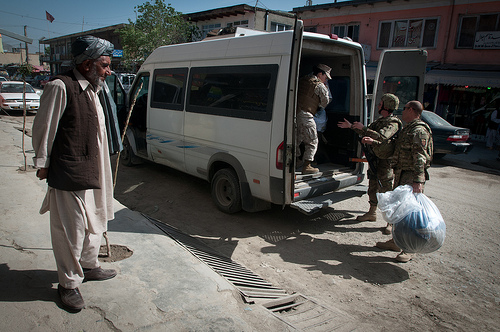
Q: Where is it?
A: This is at the street.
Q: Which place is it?
A: It is a street.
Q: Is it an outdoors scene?
A: Yes, it is outdoors.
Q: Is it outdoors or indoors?
A: It is outdoors.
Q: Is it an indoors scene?
A: No, it is outdoors.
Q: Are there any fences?
A: No, there are no fences.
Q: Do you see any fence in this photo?
A: No, there are no fences.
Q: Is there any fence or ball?
A: No, there are no fences or balls.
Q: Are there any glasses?
A: No, there are no glasses.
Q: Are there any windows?
A: Yes, there is a window.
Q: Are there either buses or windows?
A: Yes, there is a window.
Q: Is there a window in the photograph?
A: Yes, there are windows.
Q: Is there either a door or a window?
A: Yes, there are windows.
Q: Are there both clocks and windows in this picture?
A: No, there are windows but no clocks.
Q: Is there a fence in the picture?
A: No, there are no fences.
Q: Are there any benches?
A: No, there are no benches.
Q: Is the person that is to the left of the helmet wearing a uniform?
A: Yes, the person is wearing a uniform.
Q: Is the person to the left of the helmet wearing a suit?
A: No, the person is wearing a uniform.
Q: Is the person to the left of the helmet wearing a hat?
A: Yes, the person is wearing a hat.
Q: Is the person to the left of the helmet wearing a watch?
A: No, the person is wearing a hat.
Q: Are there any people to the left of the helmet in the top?
A: Yes, there is a person to the left of the helmet.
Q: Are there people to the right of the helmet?
A: No, the person is to the left of the helmet.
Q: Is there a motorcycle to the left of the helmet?
A: No, there is a person to the left of the helmet.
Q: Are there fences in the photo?
A: No, there are no fences.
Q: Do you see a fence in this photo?
A: No, there are no fences.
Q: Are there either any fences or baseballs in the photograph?
A: No, there are no fences or baseballs.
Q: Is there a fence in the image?
A: No, there are no fences.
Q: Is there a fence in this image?
A: No, there are no fences.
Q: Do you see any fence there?
A: No, there are no fences.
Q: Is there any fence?
A: No, there are no fences.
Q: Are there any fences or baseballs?
A: No, there are no fences or baseballs.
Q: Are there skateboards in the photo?
A: No, there are no skateboards.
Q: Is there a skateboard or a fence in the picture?
A: No, there are no skateboards or fences.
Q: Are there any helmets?
A: Yes, there is a helmet.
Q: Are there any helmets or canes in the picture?
A: Yes, there is a helmet.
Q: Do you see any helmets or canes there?
A: Yes, there is a helmet.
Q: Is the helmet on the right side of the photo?
A: Yes, the helmet is on the right of the image.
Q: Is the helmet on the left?
A: No, the helmet is on the right of the image.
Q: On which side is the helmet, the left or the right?
A: The helmet is on the right of the image.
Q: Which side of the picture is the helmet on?
A: The helmet is on the right of the image.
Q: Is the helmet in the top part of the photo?
A: Yes, the helmet is in the top of the image.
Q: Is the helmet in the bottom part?
A: No, the helmet is in the top of the image.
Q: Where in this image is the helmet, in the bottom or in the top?
A: The helmet is in the top of the image.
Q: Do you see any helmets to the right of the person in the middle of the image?
A: Yes, there is a helmet to the right of the person.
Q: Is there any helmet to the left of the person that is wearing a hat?
A: No, the helmet is to the right of the person.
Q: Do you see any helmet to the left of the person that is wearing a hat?
A: No, the helmet is to the right of the person.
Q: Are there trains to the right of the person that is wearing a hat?
A: No, there is a helmet to the right of the person.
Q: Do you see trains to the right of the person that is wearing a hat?
A: No, there is a helmet to the right of the person.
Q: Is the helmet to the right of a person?
A: Yes, the helmet is to the right of a person.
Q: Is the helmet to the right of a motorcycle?
A: No, the helmet is to the right of a person.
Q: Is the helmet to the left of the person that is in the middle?
A: No, the helmet is to the right of the person.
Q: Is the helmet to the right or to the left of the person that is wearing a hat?
A: The helmet is to the right of the person.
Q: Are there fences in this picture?
A: No, there are no fences.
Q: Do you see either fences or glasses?
A: No, there are no fences or glasses.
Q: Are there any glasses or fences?
A: No, there are no fences or glasses.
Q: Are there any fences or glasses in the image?
A: No, there are no fences or glasses.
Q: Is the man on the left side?
A: Yes, the man is on the left of the image.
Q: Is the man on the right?
A: No, the man is on the left of the image.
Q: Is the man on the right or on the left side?
A: The man is on the left of the image.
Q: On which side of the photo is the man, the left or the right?
A: The man is on the left of the image.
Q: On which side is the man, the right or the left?
A: The man is on the left of the image.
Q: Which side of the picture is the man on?
A: The man is on the left of the image.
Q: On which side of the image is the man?
A: The man is on the left of the image.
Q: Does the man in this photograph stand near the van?
A: Yes, the man stands near the van.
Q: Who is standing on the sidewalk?
A: The man is standing on the sidewalk.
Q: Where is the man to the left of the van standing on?
A: The man is standing on the side walk.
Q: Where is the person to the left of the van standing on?
A: The man is standing on the side walk.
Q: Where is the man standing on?
A: The man is standing on the side walk.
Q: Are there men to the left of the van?
A: Yes, there is a man to the left of the van.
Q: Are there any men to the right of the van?
A: No, the man is to the left of the van.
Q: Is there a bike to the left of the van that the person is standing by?
A: No, there is a man to the left of the van.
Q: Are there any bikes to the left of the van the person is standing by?
A: No, there is a man to the left of the van.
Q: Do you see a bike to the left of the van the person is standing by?
A: No, there is a man to the left of the van.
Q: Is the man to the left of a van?
A: Yes, the man is to the left of a van.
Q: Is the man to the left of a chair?
A: No, the man is to the left of a van.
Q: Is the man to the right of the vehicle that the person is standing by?
A: No, the man is to the left of the van.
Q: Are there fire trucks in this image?
A: No, there are no fire trucks.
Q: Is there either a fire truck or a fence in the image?
A: No, there are no fire trucks or fences.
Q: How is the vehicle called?
A: The vehicle is a van.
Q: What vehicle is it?
A: The vehicle is a van.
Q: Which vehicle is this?
A: This is a van.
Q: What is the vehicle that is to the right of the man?
A: The vehicle is a van.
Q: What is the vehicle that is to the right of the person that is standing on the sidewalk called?
A: The vehicle is a van.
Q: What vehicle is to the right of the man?
A: The vehicle is a van.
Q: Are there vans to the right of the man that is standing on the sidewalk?
A: Yes, there is a van to the right of the man.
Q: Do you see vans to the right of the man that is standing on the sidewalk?
A: Yes, there is a van to the right of the man.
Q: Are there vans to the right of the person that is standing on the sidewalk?
A: Yes, there is a van to the right of the man.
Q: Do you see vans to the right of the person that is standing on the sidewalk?
A: Yes, there is a van to the right of the man.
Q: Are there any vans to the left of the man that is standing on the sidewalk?
A: No, the van is to the right of the man.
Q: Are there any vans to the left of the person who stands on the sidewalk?
A: No, the van is to the right of the man.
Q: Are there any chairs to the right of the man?
A: No, there is a van to the right of the man.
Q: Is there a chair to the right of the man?
A: No, there is a van to the right of the man.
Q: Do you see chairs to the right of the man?
A: No, there is a van to the right of the man.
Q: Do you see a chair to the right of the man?
A: No, there is a van to the right of the man.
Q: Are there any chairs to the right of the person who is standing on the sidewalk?
A: No, there is a van to the right of the man.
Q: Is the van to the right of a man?
A: Yes, the van is to the right of a man.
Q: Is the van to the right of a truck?
A: No, the van is to the right of a man.